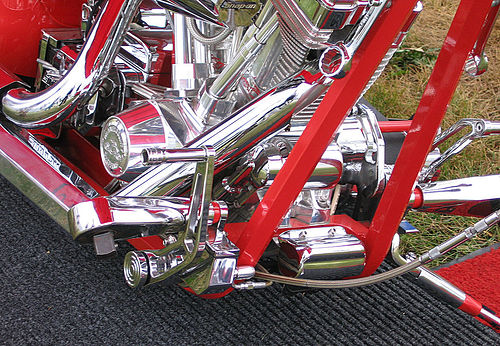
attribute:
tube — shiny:
[130, 25, 337, 231]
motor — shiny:
[4, 0, 388, 251]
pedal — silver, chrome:
[124, 148, 229, 295]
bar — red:
[321, 4, 496, 279]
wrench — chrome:
[311, 25, 360, 80]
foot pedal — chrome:
[66, 192, 228, 243]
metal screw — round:
[123, 251, 148, 291]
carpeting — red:
[440, 236, 498, 313]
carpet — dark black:
[61, 284, 396, 328]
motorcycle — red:
[1, 0, 498, 322]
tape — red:
[448, 287, 485, 318]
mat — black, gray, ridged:
[0, 178, 497, 344]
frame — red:
[238, 0, 496, 286]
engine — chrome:
[107, 86, 259, 228]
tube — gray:
[243, 207, 498, 287]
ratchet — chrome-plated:
[65, 189, 232, 261]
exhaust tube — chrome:
[31, 0, 126, 130]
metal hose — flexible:
[180, 10, 251, 50]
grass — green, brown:
[395, 30, 470, 176]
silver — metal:
[342, 48, 352, 62]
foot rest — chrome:
[105, 127, 235, 301]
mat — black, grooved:
[281, 303, 358, 334]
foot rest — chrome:
[57, 137, 225, 312]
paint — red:
[2, 0, 498, 297]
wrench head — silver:
[316, 40, 351, 88]